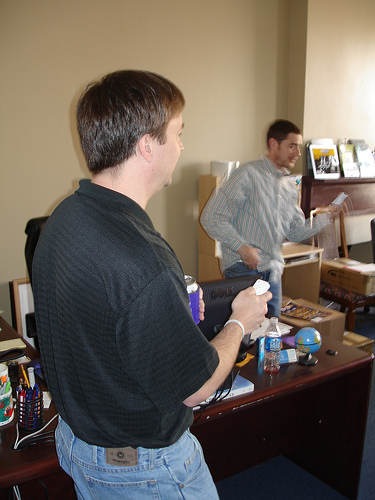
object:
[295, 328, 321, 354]
globe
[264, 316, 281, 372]
bottle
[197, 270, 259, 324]
monitor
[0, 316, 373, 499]
desk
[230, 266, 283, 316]
jeans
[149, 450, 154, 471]
loop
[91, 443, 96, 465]
loop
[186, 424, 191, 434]
loop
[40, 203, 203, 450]
shirt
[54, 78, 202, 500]
man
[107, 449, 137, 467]
logo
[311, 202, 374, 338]
chair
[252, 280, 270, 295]
controller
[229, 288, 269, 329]
hand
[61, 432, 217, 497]
blue jeans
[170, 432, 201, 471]
pocket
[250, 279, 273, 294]
video game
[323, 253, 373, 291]
box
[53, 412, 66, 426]
belt loop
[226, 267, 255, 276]
pocket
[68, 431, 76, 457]
belt loop